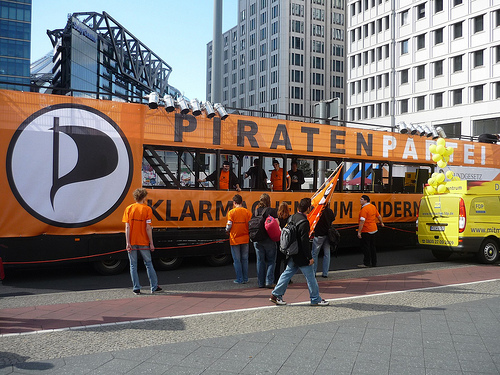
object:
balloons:
[425, 138, 460, 194]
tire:
[479, 241, 499, 263]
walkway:
[0, 276, 500, 375]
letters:
[173, 113, 374, 155]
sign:
[2, 102, 498, 226]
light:
[149, 92, 158, 109]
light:
[164, 94, 176, 112]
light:
[178, 97, 191, 113]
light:
[191, 100, 202, 116]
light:
[202, 100, 216, 118]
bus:
[2, 87, 499, 269]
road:
[1, 251, 496, 373]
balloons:
[429, 138, 454, 168]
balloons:
[426, 171, 457, 195]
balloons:
[447, 171, 461, 181]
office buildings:
[344, 0, 499, 139]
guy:
[269, 198, 328, 306]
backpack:
[280, 215, 307, 256]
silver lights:
[147, 93, 228, 120]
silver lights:
[399, 122, 447, 140]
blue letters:
[474, 202, 485, 213]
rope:
[0, 241, 225, 263]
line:
[0, 278, 500, 338]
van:
[417, 176, 500, 263]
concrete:
[324, 270, 484, 295]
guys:
[122, 190, 381, 306]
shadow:
[1, 267, 497, 373]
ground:
[1, 242, 498, 373]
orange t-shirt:
[122, 202, 153, 245]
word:
[175, 113, 197, 142]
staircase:
[143, 146, 182, 188]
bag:
[264, 215, 282, 242]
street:
[0, 236, 497, 375]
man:
[122, 188, 164, 295]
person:
[248, 194, 282, 288]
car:
[412, 164, 499, 260]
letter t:
[301, 126, 319, 152]